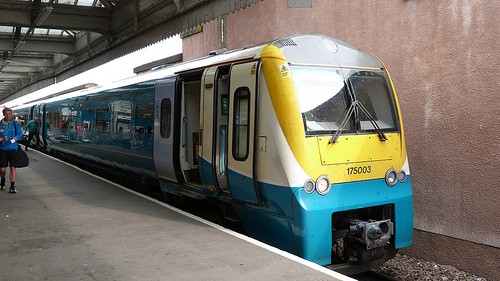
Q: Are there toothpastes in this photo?
A: No, there are no toothpastes.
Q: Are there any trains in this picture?
A: Yes, there is a train.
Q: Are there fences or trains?
A: Yes, there is a train.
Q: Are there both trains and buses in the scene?
A: No, there is a train but no buses.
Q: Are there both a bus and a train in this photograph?
A: No, there is a train but no buses.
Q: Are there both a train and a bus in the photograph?
A: No, there is a train but no buses.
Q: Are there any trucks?
A: No, there are no trucks.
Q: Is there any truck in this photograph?
A: No, there are no trucks.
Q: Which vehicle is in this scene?
A: The vehicle is a train.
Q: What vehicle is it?
A: The vehicle is a train.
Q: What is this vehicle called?
A: This is a train.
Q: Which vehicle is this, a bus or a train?
A: This is a train.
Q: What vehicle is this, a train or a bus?
A: This is a train.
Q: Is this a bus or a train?
A: This is a train.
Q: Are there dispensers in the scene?
A: No, there are no dispensers.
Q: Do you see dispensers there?
A: No, there are no dispensers.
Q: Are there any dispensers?
A: No, there are no dispensers.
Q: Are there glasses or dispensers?
A: No, there are no dispensers or glasses.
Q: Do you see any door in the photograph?
A: Yes, there is a door.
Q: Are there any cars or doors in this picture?
A: Yes, there is a door.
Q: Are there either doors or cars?
A: Yes, there is a door.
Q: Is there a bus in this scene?
A: No, there are no buses.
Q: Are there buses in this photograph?
A: No, there are no buses.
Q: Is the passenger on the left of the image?
A: Yes, the passenger is on the left of the image.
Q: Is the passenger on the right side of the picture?
A: No, the passenger is on the left of the image.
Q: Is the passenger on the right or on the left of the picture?
A: The passenger is on the left of the image.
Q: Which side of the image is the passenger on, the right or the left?
A: The passenger is on the left of the image.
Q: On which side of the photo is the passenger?
A: The passenger is on the left of the image.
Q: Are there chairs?
A: No, there are no chairs.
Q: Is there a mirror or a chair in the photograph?
A: No, there are no chairs or mirrors.